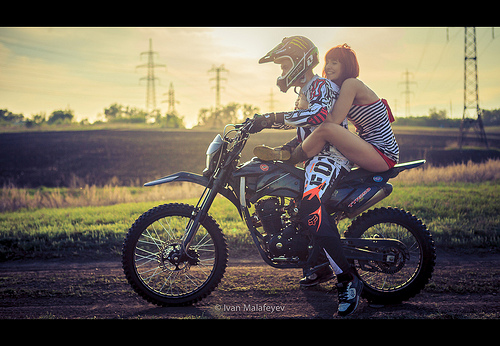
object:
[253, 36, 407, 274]
couple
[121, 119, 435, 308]
bike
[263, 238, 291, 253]
gear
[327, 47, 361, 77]
hair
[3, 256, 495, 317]
road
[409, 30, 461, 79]
wiring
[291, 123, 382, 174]
leg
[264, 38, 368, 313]
man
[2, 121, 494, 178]
field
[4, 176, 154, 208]
grass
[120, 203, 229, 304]
front tire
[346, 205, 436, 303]
back tire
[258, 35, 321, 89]
helmet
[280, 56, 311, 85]
head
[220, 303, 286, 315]
name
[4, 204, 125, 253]
grass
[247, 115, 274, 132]
hand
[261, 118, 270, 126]
handlebar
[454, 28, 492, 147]
pole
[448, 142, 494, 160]
ground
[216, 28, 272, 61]
sun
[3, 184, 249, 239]
land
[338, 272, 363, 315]
shoe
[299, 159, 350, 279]
pants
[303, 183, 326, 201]
splash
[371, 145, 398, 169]
shorts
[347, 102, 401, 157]
top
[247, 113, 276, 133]
glove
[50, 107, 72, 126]
tree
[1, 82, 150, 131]
distance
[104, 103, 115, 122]
tree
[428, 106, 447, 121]
tree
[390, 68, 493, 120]
distance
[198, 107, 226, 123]
tree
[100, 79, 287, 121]
distance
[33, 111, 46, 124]
tree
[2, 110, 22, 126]
tree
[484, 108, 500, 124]
tree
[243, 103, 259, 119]
tree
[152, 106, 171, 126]
tree